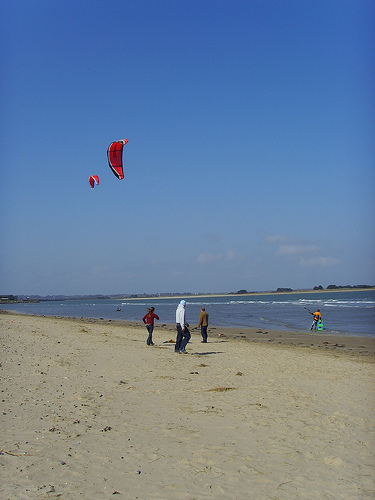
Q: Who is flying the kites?
A: Man.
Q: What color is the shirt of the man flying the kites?
A: Orange.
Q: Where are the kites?
A: Sky.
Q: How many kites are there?
A: Two.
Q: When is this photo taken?
A: Daytime.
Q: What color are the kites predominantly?
A: Red.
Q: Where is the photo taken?
A: Beach.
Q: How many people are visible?
A: Four.